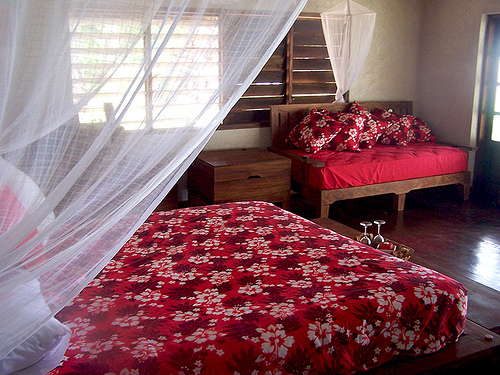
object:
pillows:
[323, 111, 365, 153]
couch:
[268, 98, 478, 219]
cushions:
[386, 112, 416, 147]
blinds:
[68, 7, 341, 129]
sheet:
[336, 159, 375, 172]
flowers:
[227, 210, 261, 222]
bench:
[304, 217, 499, 332]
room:
[0, 0, 500, 374]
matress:
[0, 201, 467, 375]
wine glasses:
[369, 219, 385, 248]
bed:
[0, 155, 469, 375]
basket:
[357, 237, 414, 261]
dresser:
[187, 146, 292, 215]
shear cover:
[318, 0, 378, 104]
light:
[476, 43, 500, 141]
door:
[469, 14, 500, 200]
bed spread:
[40, 200, 466, 375]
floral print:
[333, 255, 366, 287]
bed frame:
[370, 319, 500, 375]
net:
[0, 0, 311, 358]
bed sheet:
[275, 142, 468, 190]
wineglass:
[356, 221, 373, 248]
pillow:
[340, 101, 389, 149]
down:
[359, 236, 372, 246]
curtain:
[66, 11, 226, 130]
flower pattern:
[298, 118, 329, 147]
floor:
[414, 200, 499, 292]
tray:
[336, 233, 414, 259]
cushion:
[408, 115, 437, 143]